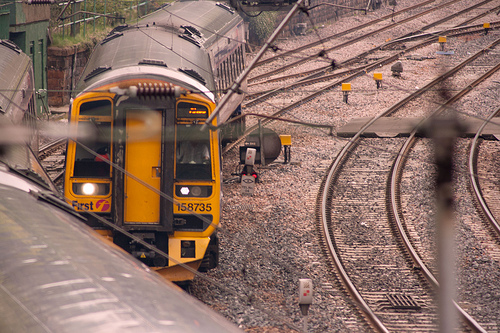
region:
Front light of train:
[81, 183, 94, 192]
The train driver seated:
[179, 135, 209, 162]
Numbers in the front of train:
[195, 202, 212, 209]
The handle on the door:
[155, 167, 159, 174]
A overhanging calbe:
[131, 175, 136, 178]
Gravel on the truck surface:
[255, 207, 300, 237]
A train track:
[334, 257, 339, 263]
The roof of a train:
[27, 255, 94, 294]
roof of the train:
[95, 28, 208, 71]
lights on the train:
[57, 181, 202, 197]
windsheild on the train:
[75, 113, 216, 170]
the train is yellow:
[133, 163, 145, 225]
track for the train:
[335, 200, 413, 292]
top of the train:
[13, 246, 160, 321]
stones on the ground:
[225, 246, 300, 313]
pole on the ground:
[314, 80, 380, 107]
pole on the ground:
[277, 273, 326, 313]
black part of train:
[106, 70, 196, 112]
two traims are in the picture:
[0, 4, 300, 330]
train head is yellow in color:
[76, 95, 286, 307]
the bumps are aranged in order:
[251, 27, 485, 138]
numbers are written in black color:
[175, 193, 238, 243]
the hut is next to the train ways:
[14, 14, 72, 103]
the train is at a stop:
[43, 16, 278, 320]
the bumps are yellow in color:
[281, 9, 453, 173]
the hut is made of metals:
[12, 8, 95, 115]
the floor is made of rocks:
[257, 170, 382, 310]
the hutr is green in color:
[9, 4, 73, 105]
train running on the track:
[57, 18, 273, 270]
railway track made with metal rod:
[323, 148, 424, 330]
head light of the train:
[67, 174, 204, 206]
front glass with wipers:
[173, 115, 220, 183]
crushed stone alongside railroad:
[318, 140, 423, 279]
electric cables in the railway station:
[213, 18, 388, 113]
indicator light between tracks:
[239, 170, 264, 185]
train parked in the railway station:
[5, 194, 127, 331]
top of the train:
[113, 26, 187, 64]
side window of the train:
[217, 53, 240, 85]